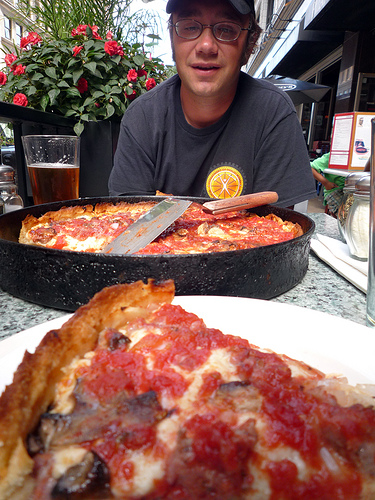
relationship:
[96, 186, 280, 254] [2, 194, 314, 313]
slicer in middle of pan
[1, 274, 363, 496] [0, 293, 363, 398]
slice on a plate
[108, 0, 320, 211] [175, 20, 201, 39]
man wearing eyeglass lens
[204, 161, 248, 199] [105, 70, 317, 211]
logo on shirt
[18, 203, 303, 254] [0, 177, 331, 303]
pizza in pan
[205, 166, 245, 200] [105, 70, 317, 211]
logo on shirt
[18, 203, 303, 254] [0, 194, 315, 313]
pizza in pan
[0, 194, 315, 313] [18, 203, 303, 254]
pan sitting on pizza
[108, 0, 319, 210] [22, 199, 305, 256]
man looking at food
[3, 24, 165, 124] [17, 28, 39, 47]
bush with flowers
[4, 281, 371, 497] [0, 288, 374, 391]
casserole on plate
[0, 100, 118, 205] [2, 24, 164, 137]
pot of carnations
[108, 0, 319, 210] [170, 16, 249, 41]
man wearing glasses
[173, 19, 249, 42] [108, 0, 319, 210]
glasses on man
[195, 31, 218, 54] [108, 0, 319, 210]
nose of man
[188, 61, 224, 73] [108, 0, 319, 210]
mouth of man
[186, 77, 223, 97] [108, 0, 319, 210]
chin of man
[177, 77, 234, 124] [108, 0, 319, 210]
neck of man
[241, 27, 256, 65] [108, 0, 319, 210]
ear of man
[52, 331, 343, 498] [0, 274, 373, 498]
cheese on pizza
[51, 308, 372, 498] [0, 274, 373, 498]
sauce on pizza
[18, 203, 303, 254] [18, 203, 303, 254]
pizza with pizza